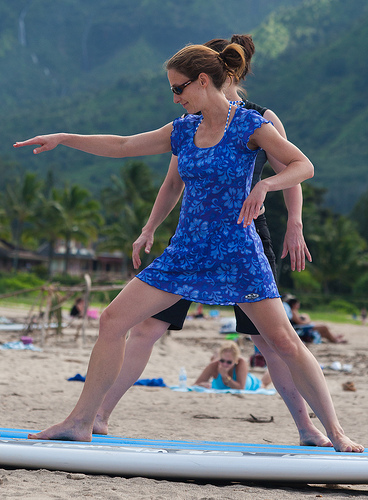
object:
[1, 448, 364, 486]
surfboard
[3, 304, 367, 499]
sand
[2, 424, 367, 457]
surfboard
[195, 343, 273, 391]
woman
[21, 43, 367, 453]
woman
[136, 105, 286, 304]
dress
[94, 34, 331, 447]
woman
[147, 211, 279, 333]
shorts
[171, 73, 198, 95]
glasses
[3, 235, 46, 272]
house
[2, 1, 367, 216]
mountain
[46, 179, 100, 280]
palm tree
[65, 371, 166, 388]
towel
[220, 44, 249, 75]
pony tail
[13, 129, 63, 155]
hand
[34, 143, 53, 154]
finger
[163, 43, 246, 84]
hair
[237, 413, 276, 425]
pipe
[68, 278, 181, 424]
leg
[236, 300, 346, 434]
leg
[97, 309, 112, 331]
knee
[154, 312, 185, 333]
edge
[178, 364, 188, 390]
bottle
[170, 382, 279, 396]
towel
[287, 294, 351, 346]
person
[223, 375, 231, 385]
watch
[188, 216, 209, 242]
flower